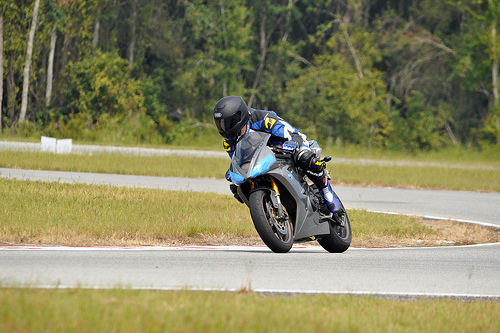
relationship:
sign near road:
[55, 135, 77, 158] [3, 136, 499, 178]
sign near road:
[36, 133, 60, 155] [3, 136, 499, 178]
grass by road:
[1, 144, 497, 194] [3, 136, 499, 178]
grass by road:
[1, 144, 497, 194] [0, 166, 499, 230]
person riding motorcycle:
[208, 95, 342, 216] [222, 123, 358, 256]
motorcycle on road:
[222, 123, 358, 256] [1, 235, 499, 302]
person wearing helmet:
[208, 95, 342, 216] [210, 91, 252, 141]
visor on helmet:
[209, 110, 242, 135] [210, 91, 252, 141]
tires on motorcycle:
[311, 182, 356, 252] [222, 123, 358, 256]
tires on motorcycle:
[245, 186, 296, 254] [222, 123, 358, 256]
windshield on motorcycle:
[229, 127, 274, 180] [222, 123, 358, 256]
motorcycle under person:
[222, 123, 358, 256] [208, 95, 342, 216]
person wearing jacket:
[208, 95, 342, 216] [227, 107, 308, 162]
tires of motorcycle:
[245, 186, 296, 254] [222, 123, 358, 256]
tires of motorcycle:
[311, 182, 356, 252] [222, 123, 358, 256]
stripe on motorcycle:
[220, 153, 279, 186] [222, 123, 358, 256]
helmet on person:
[210, 91, 252, 141] [208, 95, 342, 216]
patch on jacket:
[260, 116, 277, 133] [227, 107, 308, 162]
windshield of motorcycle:
[229, 127, 274, 180] [222, 123, 358, 256]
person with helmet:
[208, 95, 342, 216] [210, 91, 252, 141]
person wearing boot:
[208, 95, 342, 216] [314, 171, 341, 211]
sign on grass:
[55, 135, 77, 158] [1, 144, 497, 194]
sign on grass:
[36, 133, 60, 155] [1, 144, 497, 194]